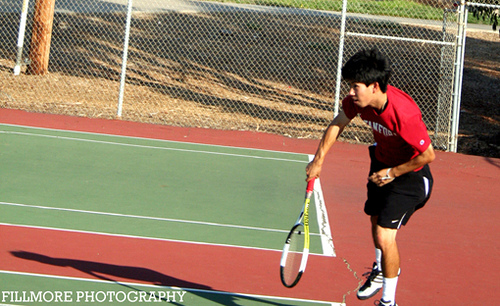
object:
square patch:
[0, 122, 338, 257]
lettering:
[0, 284, 188, 304]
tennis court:
[0, 103, 500, 306]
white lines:
[0, 198, 324, 238]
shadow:
[5, 248, 299, 306]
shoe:
[376, 295, 401, 305]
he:
[302, 48, 439, 306]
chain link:
[137, 52, 221, 111]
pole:
[26, 0, 56, 75]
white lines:
[0, 221, 324, 258]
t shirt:
[342, 83, 433, 172]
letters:
[371, 122, 379, 132]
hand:
[303, 159, 323, 183]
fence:
[0, 0, 473, 155]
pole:
[12, 0, 31, 77]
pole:
[113, 0, 133, 117]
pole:
[333, 0, 353, 117]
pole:
[448, 0, 472, 152]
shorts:
[363, 145, 437, 231]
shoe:
[355, 261, 401, 301]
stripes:
[373, 277, 385, 281]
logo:
[391, 218, 400, 224]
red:
[0, 105, 500, 306]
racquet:
[279, 171, 319, 288]